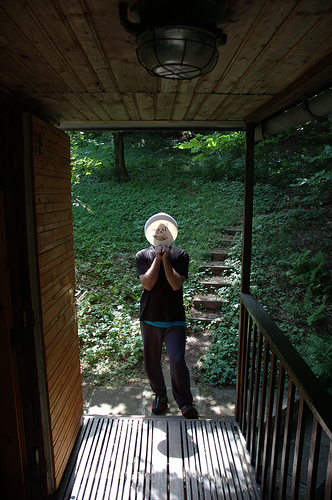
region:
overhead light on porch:
[126, 14, 236, 108]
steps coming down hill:
[178, 222, 242, 376]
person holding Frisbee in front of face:
[141, 207, 188, 253]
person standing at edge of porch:
[125, 213, 217, 429]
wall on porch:
[24, 120, 102, 498]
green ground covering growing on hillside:
[84, 198, 138, 378]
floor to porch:
[88, 403, 258, 496]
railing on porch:
[229, 278, 327, 465]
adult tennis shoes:
[141, 381, 223, 435]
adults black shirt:
[128, 242, 194, 330]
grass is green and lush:
[94, 230, 282, 363]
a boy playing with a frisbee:
[129, 206, 201, 419]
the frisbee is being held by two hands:
[132, 210, 188, 290]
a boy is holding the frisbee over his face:
[130, 210, 188, 291]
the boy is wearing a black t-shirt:
[132, 243, 187, 322]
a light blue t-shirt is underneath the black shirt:
[137, 304, 186, 328]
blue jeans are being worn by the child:
[138, 319, 191, 405]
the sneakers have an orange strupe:
[147, 392, 198, 418]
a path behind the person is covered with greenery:
[74, 136, 313, 385]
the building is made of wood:
[7, 143, 328, 493]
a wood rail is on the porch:
[236, 292, 330, 499]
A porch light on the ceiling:
[125, 0, 232, 83]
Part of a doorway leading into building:
[2, 112, 57, 497]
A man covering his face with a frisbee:
[132, 213, 197, 419]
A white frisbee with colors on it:
[142, 212, 181, 246]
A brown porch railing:
[233, 294, 329, 496]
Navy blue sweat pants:
[137, 317, 197, 407]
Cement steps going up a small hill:
[190, 227, 238, 323]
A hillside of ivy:
[82, 181, 138, 374]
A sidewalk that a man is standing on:
[83, 384, 236, 416]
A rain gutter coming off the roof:
[249, 90, 330, 146]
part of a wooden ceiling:
[252, 39, 287, 80]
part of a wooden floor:
[168, 453, 201, 477]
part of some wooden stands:
[240, 379, 305, 445]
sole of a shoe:
[189, 409, 197, 421]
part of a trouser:
[178, 371, 191, 389]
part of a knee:
[172, 355, 186, 375]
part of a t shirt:
[155, 320, 174, 331]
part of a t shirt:
[145, 293, 162, 318]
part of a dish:
[144, 216, 172, 249]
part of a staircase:
[212, 235, 229, 276]